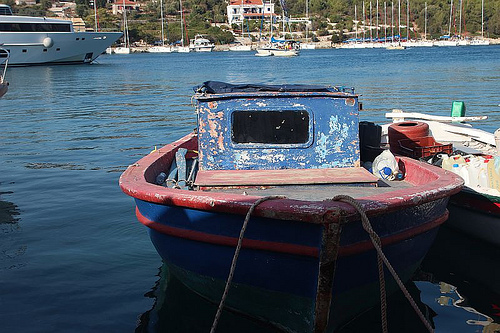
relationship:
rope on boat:
[379, 243, 385, 332] [119, 85, 465, 331]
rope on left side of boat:
[212, 195, 287, 332] [119, 85, 465, 331]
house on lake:
[226, 1, 274, 38] [147, 53, 498, 82]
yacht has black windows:
[0, 4, 124, 66] [0, 23, 71, 31]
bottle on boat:
[156, 172, 166, 184] [119, 85, 465, 331]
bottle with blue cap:
[452, 163, 469, 186] [453, 163, 458, 168]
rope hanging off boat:
[379, 243, 385, 332] [119, 85, 465, 331]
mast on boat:
[180, 0, 184, 47] [175, 46, 191, 54]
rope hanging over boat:
[212, 195, 287, 332] [119, 85, 465, 331]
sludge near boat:
[438, 281, 457, 293] [119, 85, 465, 331]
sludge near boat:
[437, 295, 454, 305] [119, 85, 465, 331]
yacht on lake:
[0, 4, 124, 66] [147, 53, 498, 82]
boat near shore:
[189, 34, 214, 53] [215, 42, 342, 49]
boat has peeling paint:
[119, 85, 465, 331] [199, 103, 230, 167]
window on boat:
[233, 112, 308, 144] [119, 85, 465, 331]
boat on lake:
[119, 85, 465, 331] [147, 53, 498, 82]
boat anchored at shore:
[189, 34, 214, 53] [215, 42, 342, 49]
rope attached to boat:
[212, 195, 287, 332] [119, 85, 465, 331]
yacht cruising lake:
[0, 4, 124, 66] [147, 53, 498, 82]